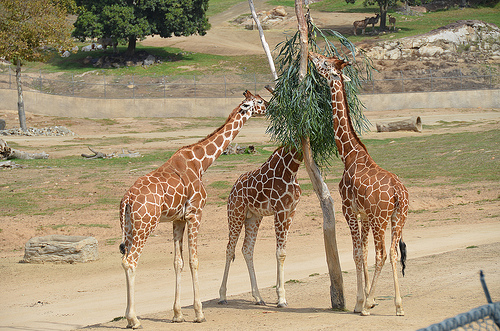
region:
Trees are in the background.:
[0, 0, 212, 127]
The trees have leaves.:
[0, 0, 210, 130]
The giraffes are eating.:
[114, 50, 411, 326]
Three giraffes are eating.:
[115, 50, 410, 329]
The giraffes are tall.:
[116, 48, 410, 329]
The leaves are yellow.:
[1, 0, 75, 67]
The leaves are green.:
[68, 0, 213, 42]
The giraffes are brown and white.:
[119, 49, 407, 329]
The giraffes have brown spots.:
[116, 49, 407, 329]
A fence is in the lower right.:
[411, 295, 498, 330]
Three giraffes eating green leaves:
[100, 42, 421, 325]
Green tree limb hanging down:
[255, 5, 355, 145]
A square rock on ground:
[15, 225, 100, 271]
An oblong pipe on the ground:
[370, 110, 431, 146]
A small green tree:
[0, 20, 65, 125]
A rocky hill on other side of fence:
[360, 15, 495, 65]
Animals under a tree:
[340, 1, 406, 37]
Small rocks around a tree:
[5, 116, 72, 137]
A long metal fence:
[30, 70, 499, 95]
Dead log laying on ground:
[0, 126, 48, 169]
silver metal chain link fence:
[441, 298, 492, 329]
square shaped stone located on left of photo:
[24, 220, 114, 285]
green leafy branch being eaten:
[277, 64, 352, 140]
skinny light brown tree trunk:
[313, 177, 352, 310]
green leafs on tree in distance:
[102, 2, 185, 49]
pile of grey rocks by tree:
[43, 121, 95, 158]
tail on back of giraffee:
[120, 186, 135, 270]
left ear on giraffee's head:
[329, 62, 361, 90]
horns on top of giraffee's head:
[235, 85, 263, 100]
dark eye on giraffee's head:
[256, 97, 268, 111]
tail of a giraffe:
[403, 238, 409, 253]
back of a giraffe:
[360, 188, 376, 189]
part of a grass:
[280, 108, 294, 130]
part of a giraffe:
[155, 190, 174, 193]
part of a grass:
[416, 142, 436, 159]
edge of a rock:
[61, 220, 82, 254]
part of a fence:
[118, 89, 135, 116]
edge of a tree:
[297, 108, 305, 147]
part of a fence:
[420, 93, 433, 103]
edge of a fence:
[111, 93, 119, 105]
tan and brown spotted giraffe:
[98, 85, 285, 329]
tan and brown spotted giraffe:
[256, 129, 323, 314]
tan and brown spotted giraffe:
[303, 37, 417, 319]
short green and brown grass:
[8, 165, 29, 197]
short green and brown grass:
[72, 159, 87, 189]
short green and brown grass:
[413, 137, 463, 179]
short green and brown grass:
[455, 135, 497, 205]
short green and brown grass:
[105, 76, 140, 124]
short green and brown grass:
[41, 106, 109, 166]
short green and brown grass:
[438, 240, 479, 275]